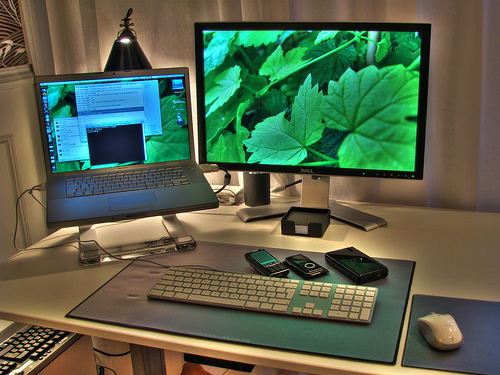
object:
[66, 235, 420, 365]
mat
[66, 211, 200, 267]
computer stand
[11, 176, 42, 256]
cord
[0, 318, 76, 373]
keyboard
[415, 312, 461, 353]
mouse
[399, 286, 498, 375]
pad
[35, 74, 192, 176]
screen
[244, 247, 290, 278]
cell phone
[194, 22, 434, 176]
monitor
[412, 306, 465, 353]
ropes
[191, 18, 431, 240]
computer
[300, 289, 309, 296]
key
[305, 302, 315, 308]
key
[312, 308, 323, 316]
key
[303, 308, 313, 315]
key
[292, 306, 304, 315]
key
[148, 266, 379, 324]
keyboard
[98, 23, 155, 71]
lamp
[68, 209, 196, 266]
platform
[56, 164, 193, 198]
keyboard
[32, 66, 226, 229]
computer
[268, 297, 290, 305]
key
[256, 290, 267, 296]
key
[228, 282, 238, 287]
key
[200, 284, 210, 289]
key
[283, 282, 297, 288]
key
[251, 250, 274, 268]
screen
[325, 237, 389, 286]
phones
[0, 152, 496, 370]
desk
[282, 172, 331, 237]
stand